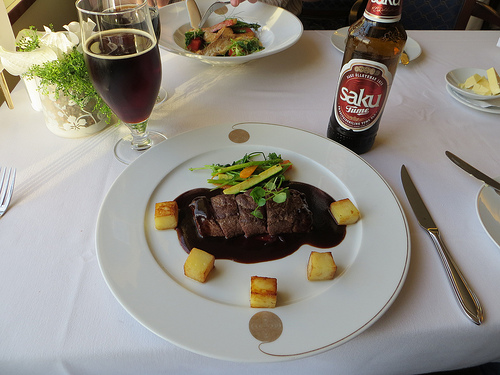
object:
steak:
[194, 186, 314, 238]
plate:
[97, 125, 412, 365]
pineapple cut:
[250, 275, 280, 307]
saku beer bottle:
[327, 0, 408, 154]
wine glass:
[76, 1, 170, 165]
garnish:
[189, 150, 292, 218]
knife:
[401, 163, 485, 325]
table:
[1, 31, 500, 375]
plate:
[444, 68, 500, 103]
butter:
[464, 68, 500, 93]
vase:
[25, 76, 110, 137]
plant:
[21, 24, 112, 122]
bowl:
[157, 1, 305, 65]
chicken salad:
[183, 19, 264, 55]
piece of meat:
[185, 1, 204, 29]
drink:
[83, 29, 164, 123]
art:
[249, 312, 285, 343]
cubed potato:
[155, 201, 178, 230]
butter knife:
[445, 150, 499, 193]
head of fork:
[0, 168, 14, 217]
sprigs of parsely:
[249, 182, 288, 215]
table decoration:
[0, 17, 94, 77]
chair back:
[402, 0, 497, 30]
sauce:
[174, 182, 347, 265]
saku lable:
[334, 58, 392, 131]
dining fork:
[200, 1, 230, 28]